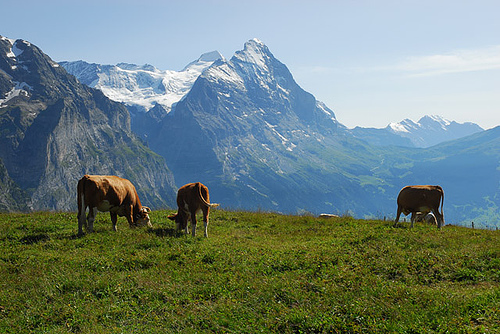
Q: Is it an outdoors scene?
A: Yes, it is outdoors.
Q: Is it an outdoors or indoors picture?
A: It is outdoors.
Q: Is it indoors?
A: No, it is outdoors.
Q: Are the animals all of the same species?
A: Yes, all the animals are cows.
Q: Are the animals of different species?
A: No, all the animals are cows.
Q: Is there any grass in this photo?
A: Yes, there is grass.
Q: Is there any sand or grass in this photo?
A: Yes, there is grass.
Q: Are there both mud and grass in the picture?
A: No, there is grass but no mud.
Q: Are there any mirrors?
A: No, there are no mirrors.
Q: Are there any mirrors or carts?
A: No, there are no mirrors or carts.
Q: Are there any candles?
A: No, there are no candles.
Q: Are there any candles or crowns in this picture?
A: No, there are no candles or crowns.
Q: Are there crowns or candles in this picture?
A: No, there are no candles or crowns.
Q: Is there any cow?
A: Yes, there are cows.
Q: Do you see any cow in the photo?
A: Yes, there are cows.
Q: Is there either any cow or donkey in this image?
A: Yes, there are cows.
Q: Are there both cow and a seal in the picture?
A: No, there are cows but no seals.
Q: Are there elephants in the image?
A: No, there are no elephants.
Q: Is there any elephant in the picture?
A: No, there are no elephants.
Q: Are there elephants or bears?
A: No, there are no elephants or bears.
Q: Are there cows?
A: Yes, there are cows.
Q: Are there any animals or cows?
A: Yes, there are cows.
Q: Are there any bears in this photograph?
A: No, there are no bears.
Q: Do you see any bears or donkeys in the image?
A: No, there are no bears or donkeys.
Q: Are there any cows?
A: Yes, there are cows.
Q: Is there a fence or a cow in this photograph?
A: Yes, there are cows.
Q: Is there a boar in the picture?
A: No, there are no boars.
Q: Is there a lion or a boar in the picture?
A: No, there are no boars or lions.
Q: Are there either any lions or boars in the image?
A: No, there are no boars or lions.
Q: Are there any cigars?
A: No, there are no cigars.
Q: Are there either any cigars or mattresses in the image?
A: No, there are no cigars or mattresses.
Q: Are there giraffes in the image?
A: No, there are no giraffes.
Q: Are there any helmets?
A: No, there are no helmets.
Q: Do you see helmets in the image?
A: No, there are no helmets.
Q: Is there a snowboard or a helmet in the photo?
A: No, there are no helmets or snowboards.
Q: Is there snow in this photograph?
A: Yes, there is snow.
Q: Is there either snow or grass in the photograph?
A: Yes, there is snow.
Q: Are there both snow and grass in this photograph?
A: Yes, there are both snow and grass.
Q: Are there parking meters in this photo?
A: No, there are no parking meters.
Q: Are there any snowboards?
A: No, there are no snowboards.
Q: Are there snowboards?
A: No, there are no snowboards.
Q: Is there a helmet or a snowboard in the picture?
A: No, there are no snowboards or helmets.